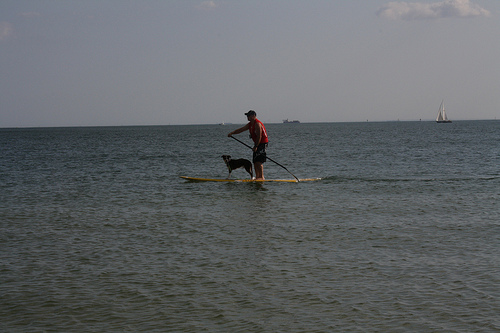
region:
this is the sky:
[61, 26, 168, 72]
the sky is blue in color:
[296, 15, 356, 88]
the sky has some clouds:
[368, 3, 483, 13]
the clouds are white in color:
[388, 8, 485, 18]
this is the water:
[45, 132, 142, 172]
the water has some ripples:
[148, 207, 311, 288]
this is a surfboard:
[181, 175, 312, 187]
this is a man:
[233, 110, 273, 172]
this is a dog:
[216, 152, 258, 177]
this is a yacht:
[434, 102, 454, 132]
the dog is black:
[229, 157, 241, 176]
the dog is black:
[221, 156, 244, 178]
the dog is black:
[241, 151, 251, 184]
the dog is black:
[230, 163, 242, 182]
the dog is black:
[234, 155, 253, 178]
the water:
[262, 256, 308, 306]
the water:
[262, 245, 313, 270]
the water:
[317, 273, 369, 330]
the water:
[267, 210, 329, 290]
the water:
[297, 254, 348, 307]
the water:
[277, 279, 328, 330]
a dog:
[215, 145, 282, 210]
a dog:
[211, 148, 249, 182]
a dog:
[200, 136, 260, 182]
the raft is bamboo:
[281, 172, 294, 208]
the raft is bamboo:
[273, 165, 290, 192]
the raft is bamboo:
[275, 172, 284, 182]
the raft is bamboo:
[276, 169, 287, 189]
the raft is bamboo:
[277, 180, 282, 187]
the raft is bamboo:
[280, 175, 285, 188]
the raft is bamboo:
[285, 178, 295, 191]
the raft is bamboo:
[267, 168, 286, 187]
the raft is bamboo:
[276, 176, 289, 186]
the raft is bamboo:
[277, 178, 284, 183]